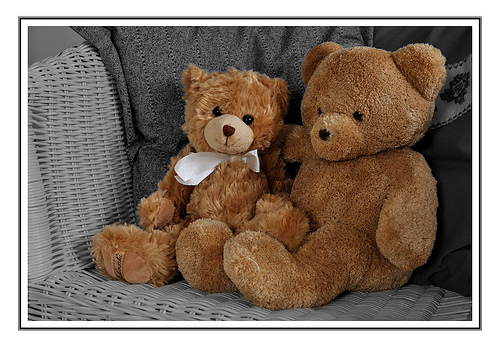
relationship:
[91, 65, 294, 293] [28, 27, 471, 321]
teddy bear in chair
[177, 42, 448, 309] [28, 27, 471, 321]
teddy bear in chair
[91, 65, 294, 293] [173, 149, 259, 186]
teddy bear has bow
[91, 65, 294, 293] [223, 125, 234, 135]
teddy bear has nose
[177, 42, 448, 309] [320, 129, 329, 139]
teddy bear has nose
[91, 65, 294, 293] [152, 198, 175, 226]
teddy bear has front paw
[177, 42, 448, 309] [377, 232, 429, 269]
teddy bear has front paw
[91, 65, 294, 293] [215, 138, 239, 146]
teddy bear has mouth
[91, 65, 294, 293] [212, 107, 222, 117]
teddy bear has eye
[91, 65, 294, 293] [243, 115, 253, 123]
teddy bear has eye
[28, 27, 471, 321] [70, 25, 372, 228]
chair has blanket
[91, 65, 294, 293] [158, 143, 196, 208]
teddy bear has arm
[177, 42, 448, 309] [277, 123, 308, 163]
teddy bear has arm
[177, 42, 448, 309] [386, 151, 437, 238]
teddy bear has arm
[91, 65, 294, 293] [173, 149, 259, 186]
teddy bear wearing bow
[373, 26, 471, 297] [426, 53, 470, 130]
blanket has trim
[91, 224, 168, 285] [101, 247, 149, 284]
paw has pad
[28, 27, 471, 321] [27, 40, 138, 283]
chair has arm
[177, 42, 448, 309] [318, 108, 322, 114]
teddy bear has eye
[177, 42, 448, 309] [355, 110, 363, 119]
teddy bear has eye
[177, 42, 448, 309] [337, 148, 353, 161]
teddy bear has mouth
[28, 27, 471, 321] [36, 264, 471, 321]
chair has seat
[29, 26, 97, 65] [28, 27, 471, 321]
wall behind chair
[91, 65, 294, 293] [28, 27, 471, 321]
teddy bear on chair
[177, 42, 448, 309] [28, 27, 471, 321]
teddy bear on chair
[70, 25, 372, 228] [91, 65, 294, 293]
blanket behind teddy bear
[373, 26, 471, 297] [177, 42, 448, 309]
blanket behind teddy bear